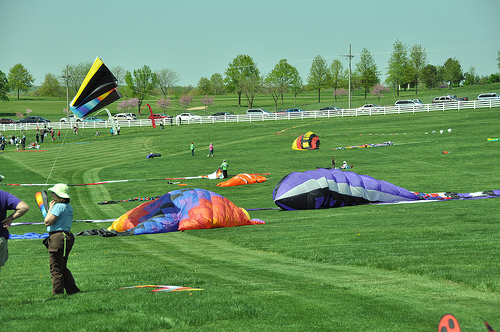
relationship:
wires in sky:
[352, 45, 484, 59] [3, 0, 484, 84]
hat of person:
[44, 180, 74, 198] [43, 182, 80, 294]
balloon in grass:
[73, 188, 266, 236] [0, 83, 484, 326]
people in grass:
[3, 123, 81, 152] [0, 83, 484, 326]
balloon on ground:
[104, 190, 255, 237] [13, 99, 481, 325]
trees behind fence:
[9, 43, 479, 102] [8, 95, 481, 130]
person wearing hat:
[38, 182, 76, 294] [50, 181, 70, 198]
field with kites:
[18, 126, 480, 330] [93, 150, 484, 230]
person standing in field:
[43, 182, 80, 294] [11, 100, 483, 328]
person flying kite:
[43, 182, 80, 294] [66, 56, 121, 124]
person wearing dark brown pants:
[43, 182, 80, 294] [44, 224, 76, 328]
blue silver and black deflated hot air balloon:
[255, 188, 485, 209] [318, 151, 340, 222]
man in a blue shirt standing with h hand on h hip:
[1, 174, 34, 226] [1, 225, 11, 256]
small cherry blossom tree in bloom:
[162, 134, 175, 162] [156, 66, 179, 122]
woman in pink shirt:
[205, 139, 217, 158] [206, 145, 213, 148]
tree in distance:
[14, 58, 32, 125] [13, 99, 489, 163]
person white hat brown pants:
[43, 182, 80, 294] [46, 226, 83, 332]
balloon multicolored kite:
[73, 188, 266, 236] [162, 200, 212, 262]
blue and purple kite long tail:
[274, 168, 500, 200] [405, 194, 493, 205]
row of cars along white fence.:
[172, 50, 492, 112] [232, 110, 401, 118]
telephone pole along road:
[343, 50, 355, 101] [166, 102, 188, 116]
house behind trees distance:
[418, 76, 483, 91] [239, 99, 258, 110]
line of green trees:
[214, 84, 405, 117] [134, 99, 145, 105]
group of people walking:
[1, 79, 84, 180] [22, 151, 44, 163]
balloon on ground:
[273, 168, 422, 211] [300, 225, 434, 263]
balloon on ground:
[73, 188, 266, 236] [264, 238, 384, 328]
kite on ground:
[270, 109, 341, 173] [380, 138, 437, 172]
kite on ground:
[200, 152, 269, 198] [222, 144, 283, 183]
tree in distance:
[205, 45, 273, 119] [174, 38, 368, 112]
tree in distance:
[228, 45, 301, 122] [194, 30, 427, 131]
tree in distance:
[7, 41, 63, 115] [130, 13, 315, 94]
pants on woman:
[30, 229, 101, 304] [24, 175, 127, 330]